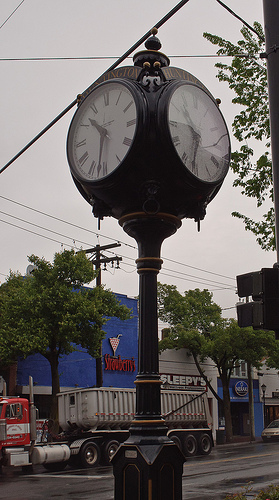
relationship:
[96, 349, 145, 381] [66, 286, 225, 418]
logo aside building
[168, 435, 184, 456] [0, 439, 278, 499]
wheel on ground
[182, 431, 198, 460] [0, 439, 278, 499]
tire on ground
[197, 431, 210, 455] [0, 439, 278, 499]
wheel on ground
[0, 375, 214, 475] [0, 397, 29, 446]
truck has cab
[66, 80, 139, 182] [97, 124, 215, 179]
clock has white face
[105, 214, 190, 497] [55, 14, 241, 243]
post with clock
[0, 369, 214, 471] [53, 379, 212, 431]
truck carrying white box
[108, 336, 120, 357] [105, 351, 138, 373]
glass on a logo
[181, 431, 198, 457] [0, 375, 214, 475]
tire near by truck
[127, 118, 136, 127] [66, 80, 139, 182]
number 3 on clock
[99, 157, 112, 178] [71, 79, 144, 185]
6 on clock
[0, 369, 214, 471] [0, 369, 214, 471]
truck hauling truck